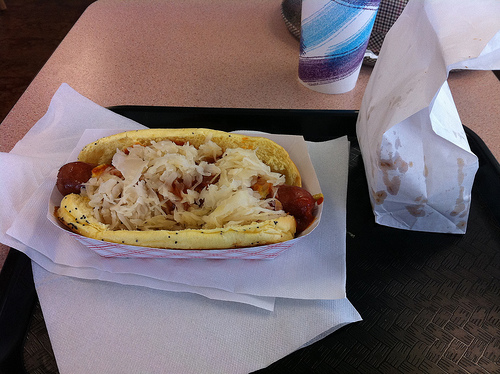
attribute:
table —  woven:
[359, 254, 492, 374]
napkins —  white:
[33, 270, 360, 372]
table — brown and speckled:
[86, 75, 289, 104]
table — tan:
[21, 64, 331, 125]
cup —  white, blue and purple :
[318, 99, 332, 106]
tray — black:
[242, 211, 475, 374]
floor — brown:
[16, 100, 33, 101]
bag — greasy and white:
[373, 153, 465, 201]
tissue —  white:
[79, 307, 104, 323]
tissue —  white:
[82, 218, 257, 331]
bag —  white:
[381, 91, 473, 251]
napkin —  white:
[77, 265, 313, 296]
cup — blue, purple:
[297, 0, 381, 94]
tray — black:
[2, 93, 496, 370]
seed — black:
[271, 219, 278, 229]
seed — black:
[171, 237, 181, 245]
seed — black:
[164, 231, 173, 241]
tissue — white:
[39, 276, 358, 372]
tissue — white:
[17, 222, 348, 303]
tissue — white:
[0, 85, 130, 238]